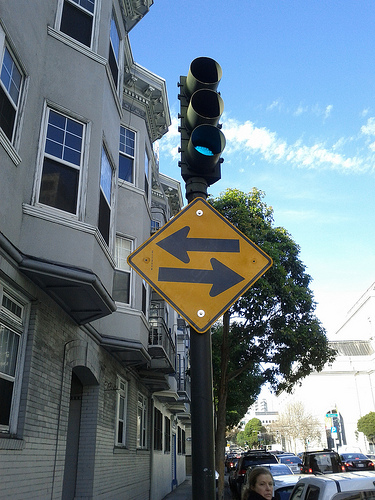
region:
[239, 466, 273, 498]
The woman has brown hair.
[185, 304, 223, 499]
The sign post is black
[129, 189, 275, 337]
The sign is yellow.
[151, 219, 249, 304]
The sign has two arrows on it.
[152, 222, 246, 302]
The arrows are black.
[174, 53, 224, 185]
The post has a traffic light on it.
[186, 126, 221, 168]
The green light is lit up.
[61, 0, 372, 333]
The sky is blue.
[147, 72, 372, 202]
The clouds are white and wispy.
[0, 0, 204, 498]
The building has many balconies.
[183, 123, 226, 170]
The green street light on the sign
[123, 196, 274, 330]
The yellow street sign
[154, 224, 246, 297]
The black arrows on the yellow sign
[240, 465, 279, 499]
The face of the woman looking towards the camera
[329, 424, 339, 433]
The blue parking sign in the backgroound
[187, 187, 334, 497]
The tree behind the street sign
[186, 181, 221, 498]
The pole with the street light on it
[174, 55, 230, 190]
The street light on top of the pole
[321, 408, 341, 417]
The green street sign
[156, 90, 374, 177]
The line of clouds in the sky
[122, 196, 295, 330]
Yellow directional sign on street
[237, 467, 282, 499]
Woman waiting on street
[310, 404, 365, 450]
White arch way on building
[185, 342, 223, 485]
Black pole holding sign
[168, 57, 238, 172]
Stop light above street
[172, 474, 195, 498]
Cement sidewalk along street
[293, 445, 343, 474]
Black car driving down street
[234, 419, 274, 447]
Cluster of trees on sidewalk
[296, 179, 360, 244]
clear blue sky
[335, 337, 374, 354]
Grey awning on building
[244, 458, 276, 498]
woman crossing road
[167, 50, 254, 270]
traffic light with green light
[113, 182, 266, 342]
road sign on side of traffic light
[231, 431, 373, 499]
Cars driving on road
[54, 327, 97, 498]
doorway to apartment building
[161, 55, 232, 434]
traffic light on side of road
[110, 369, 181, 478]
windows on side of building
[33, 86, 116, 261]
windows on building facing road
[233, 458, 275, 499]
woman turned to the right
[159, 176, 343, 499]
tree on sidewalk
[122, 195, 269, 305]
the sign is diamond shaped with two arrows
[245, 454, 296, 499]
the woman is looking towards the camera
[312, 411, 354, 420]
a green street sign with white letters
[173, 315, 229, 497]
a black pole holding a sign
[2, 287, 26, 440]
a white window with many panes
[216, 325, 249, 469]
the trunk of a slender tree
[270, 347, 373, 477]
a large white building in the distance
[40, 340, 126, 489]
an arched doorway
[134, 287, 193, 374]
a metal gray balcony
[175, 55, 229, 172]
a traffic signal showing green